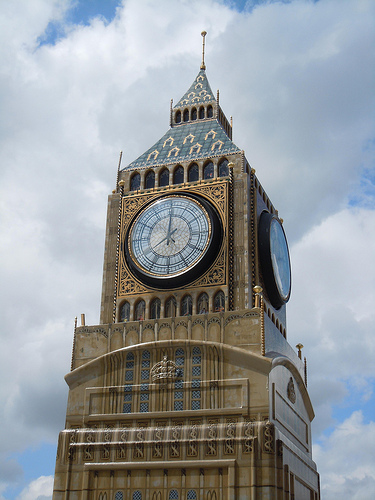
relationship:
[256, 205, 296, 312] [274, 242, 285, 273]
clock has dials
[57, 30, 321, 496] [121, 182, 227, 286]
tower has clock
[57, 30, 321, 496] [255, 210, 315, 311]
tower has clock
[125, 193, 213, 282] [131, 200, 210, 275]
clock has lines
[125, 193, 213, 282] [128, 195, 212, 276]
clock has numerals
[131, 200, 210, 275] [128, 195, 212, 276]
lines for numerals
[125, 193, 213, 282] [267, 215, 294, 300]
clock has cover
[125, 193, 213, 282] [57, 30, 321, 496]
clock on tower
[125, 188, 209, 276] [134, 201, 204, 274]
clock has clock face